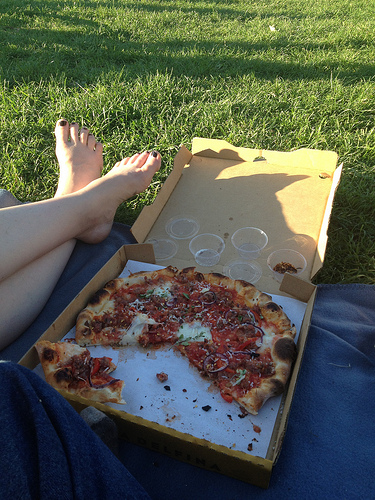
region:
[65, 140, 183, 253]
leg of a person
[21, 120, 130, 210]
leg of a person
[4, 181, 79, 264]
leg of a person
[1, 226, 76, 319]
leg of a person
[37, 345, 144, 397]
pizza in a box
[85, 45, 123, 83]
grass on a field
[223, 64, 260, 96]
grass on a field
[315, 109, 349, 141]
grass on a field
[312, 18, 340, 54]
grass on a field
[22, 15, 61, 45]
grass on a field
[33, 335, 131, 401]
Partially eaten slice of pizza in the box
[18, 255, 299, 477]
Partially-eaten pizza in a box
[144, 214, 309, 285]
Small plastic containers and lids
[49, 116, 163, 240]
Person's bare feet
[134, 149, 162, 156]
Black nail polish on toenails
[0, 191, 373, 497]
Blue blanket on the ground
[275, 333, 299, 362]
Burnt area on pizza crust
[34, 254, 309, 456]
White paper under the pizza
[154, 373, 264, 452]
Crumbs in the pizza box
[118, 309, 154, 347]
Cheese on the pizza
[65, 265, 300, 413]
Pizza being eaten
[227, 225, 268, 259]
Clear plastic container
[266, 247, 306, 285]
Clear plastic container with seasoning inside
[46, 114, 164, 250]
Female feet with dark nail polish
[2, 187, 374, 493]
Blue fleece picnic blanket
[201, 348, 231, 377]
Circle of red onion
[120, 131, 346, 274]
Top half of a pizza box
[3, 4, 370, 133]
Green grass on a lawn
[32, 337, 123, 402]
Pizza slice in the midst of being eaten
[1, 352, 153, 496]
A knee clad in denim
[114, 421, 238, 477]
the pizza place's name seems to be Delfina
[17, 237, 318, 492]
a partially consumed pizza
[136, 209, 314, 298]
the pizza came with several toppings in containers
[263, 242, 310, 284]
a little bit of one topping was not used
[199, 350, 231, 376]
slice red onions on this pizza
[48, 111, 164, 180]
the pizza eater paints her toenails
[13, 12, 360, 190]
eating pizza in a grassy area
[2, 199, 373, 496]
the picnic blanket for pizza eating is blue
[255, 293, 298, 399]
the pizza crust has been well browned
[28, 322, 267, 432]
2 1/2 slices from this pizza have been eaten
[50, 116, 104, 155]
Painted toe nails.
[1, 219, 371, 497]
Blue blanket on the ground.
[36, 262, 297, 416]
A half eaten pizza.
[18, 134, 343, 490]
A half eaten pizza.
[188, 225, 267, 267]
Empty plastic containers.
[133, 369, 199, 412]
Pizza crumbs on white paper.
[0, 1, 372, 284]
The green grass of a field.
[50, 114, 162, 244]
Feet on top of grass.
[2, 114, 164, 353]
The legs of a female.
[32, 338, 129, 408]
A slice of half eaten pizza.